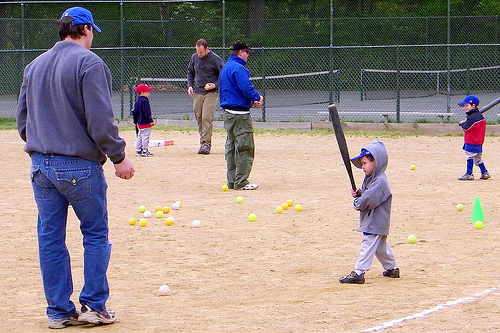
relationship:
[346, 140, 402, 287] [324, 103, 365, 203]
boy holding baseball bat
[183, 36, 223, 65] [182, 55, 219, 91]
man wearing sweater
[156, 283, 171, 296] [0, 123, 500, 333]
ball on field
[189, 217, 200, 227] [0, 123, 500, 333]
baseball on field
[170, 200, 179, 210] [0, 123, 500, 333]
baseball on field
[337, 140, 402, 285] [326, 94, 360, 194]
boy holding bat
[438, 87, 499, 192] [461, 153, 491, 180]
boy wearing socks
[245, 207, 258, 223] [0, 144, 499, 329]
ball lying on ground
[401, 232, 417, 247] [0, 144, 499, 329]
ball lying on ground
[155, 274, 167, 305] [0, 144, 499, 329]
ball lying on ground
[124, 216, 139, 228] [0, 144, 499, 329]
ball lying on ground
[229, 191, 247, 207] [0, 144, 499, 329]
ball lying on ground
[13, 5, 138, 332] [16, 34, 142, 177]
man wearing shirt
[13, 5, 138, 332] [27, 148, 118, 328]
man wearing blue jeans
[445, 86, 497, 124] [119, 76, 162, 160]
cap on boy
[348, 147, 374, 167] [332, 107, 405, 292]
hat on child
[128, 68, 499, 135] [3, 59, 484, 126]
nets on field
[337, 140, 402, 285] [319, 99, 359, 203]
boy holding bat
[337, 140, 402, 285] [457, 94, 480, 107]
boy wearing cap